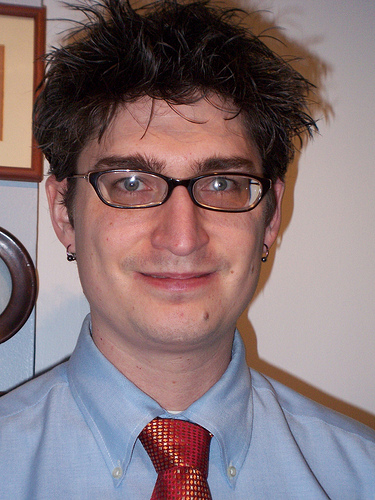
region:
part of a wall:
[314, 257, 338, 292]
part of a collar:
[214, 422, 238, 464]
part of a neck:
[158, 375, 189, 406]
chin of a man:
[158, 322, 194, 349]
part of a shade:
[305, 382, 322, 400]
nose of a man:
[171, 236, 192, 252]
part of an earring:
[262, 245, 271, 263]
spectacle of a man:
[98, 169, 241, 208]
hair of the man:
[53, 33, 86, 143]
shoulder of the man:
[309, 411, 367, 442]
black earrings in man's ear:
[51, 241, 93, 274]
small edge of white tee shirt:
[153, 403, 205, 420]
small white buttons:
[219, 461, 249, 485]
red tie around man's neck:
[126, 396, 234, 498]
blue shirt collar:
[50, 308, 288, 448]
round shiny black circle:
[3, 222, 49, 335]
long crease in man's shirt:
[256, 368, 335, 497]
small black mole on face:
[191, 308, 229, 331]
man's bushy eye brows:
[72, 135, 275, 209]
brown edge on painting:
[15, 159, 50, 199]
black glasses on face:
[68, 166, 271, 212]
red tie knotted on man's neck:
[137, 415, 214, 498]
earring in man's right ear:
[61, 240, 76, 263]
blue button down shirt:
[0, 310, 373, 498]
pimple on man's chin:
[163, 298, 191, 323]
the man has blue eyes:
[119, 176, 140, 191]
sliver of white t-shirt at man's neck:
[166, 409, 185, 414]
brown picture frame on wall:
[0, 226, 39, 352]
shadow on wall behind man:
[233, 1, 374, 429]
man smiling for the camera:
[136, 264, 221, 290]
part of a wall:
[335, 171, 359, 234]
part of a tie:
[165, 453, 205, 495]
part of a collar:
[209, 408, 235, 471]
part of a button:
[227, 470, 243, 487]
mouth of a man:
[141, 267, 199, 295]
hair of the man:
[192, 34, 276, 91]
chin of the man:
[158, 318, 201, 348]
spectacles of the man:
[104, 164, 190, 195]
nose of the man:
[147, 221, 216, 255]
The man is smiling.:
[38, 26, 323, 354]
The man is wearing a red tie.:
[129, 408, 219, 493]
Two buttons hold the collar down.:
[90, 390, 257, 495]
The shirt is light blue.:
[15, 324, 157, 489]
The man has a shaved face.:
[63, 98, 281, 340]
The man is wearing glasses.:
[61, 135, 286, 227]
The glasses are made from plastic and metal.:
[60, 153, 277, 228]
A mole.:
[191, 300, 212, 326]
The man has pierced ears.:
[32, 56, 310, 334]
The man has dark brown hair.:
[21, 8, 309, 333]